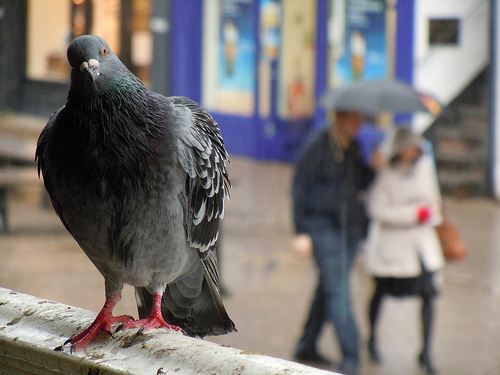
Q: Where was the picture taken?
A: It was taken at the street.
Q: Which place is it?
A: It is a street.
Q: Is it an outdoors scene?
A: Yes, it is outdoors.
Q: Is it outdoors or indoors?
A: It is outdoors.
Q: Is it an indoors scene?
A: No, it is outdoors.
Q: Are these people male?
A: No, they are both male and female.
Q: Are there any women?
A: Yes, there is a woman.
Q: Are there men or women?
A: Yes, there is a woman.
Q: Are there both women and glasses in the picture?
A: No, there is a woman but no glasses.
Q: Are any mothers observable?
A: No, there are no mothers.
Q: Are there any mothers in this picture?
A: No, there are no mothers.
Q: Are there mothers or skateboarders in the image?
A: No, there are no mothers or skateboarders.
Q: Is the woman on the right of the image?
A: Yes, the woman is on the right of the image.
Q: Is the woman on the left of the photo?
A: No, the woman is on the right of the image.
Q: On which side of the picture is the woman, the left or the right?
A: The woman is on the right of the image.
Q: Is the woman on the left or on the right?
A: The woman is on the right of the image.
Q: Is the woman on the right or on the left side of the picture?
A: The woman is on the right of the image.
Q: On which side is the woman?
A: The woman is on the right of the image.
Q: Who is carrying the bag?
A: The woman is carrying the bag.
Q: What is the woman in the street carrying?
A: The woman is carrying a bag.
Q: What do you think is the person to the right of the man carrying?
A: The woman is carrying a bag.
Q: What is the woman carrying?
A: The woman is carrying a bag.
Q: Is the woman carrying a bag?
A: Yes, the woman is carrying a bag.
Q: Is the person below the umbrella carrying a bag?
A: Yes, the woman is carrying a bag.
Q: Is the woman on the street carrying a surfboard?
A: No, the woman is carrying a bag.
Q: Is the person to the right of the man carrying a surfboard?
A: No, the woman is carrying a bag.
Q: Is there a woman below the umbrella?
A: Yes, there is a woman below the umbrella.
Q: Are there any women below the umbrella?
A: Yes, there is a woman below the umbrella.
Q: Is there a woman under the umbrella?
A: Yes, there is a woman under the umbrella.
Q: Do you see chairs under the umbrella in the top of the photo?
A: No, there is a woman under the umbrella.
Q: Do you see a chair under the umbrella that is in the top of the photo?
A: No, there is a woman under the umbrella.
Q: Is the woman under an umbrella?
A: Yes, the woman is under an umbrella.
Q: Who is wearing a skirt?
A: The woman is wearing a skirt.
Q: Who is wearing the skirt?
A: The woman is wearing a skirt.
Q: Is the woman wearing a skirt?
A: Yes, the woman is wearing a skirt.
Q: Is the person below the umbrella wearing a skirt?
A: Yes, the woman is wearing a skirt.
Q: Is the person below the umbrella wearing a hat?
A: No, the woman is wearing a skirt.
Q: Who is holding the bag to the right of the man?
A: The woman is holding the bag.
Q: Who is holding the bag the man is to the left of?
A: The woman is holding the bag.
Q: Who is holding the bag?
A: The woman is holding the bag.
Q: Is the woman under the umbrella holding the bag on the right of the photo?
A: Yes, the woman is holding the bag.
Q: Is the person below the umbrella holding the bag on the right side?
A: Yes, the woman is holding the bag.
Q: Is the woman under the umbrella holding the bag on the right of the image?
A: Yes, the woman is holding the bag.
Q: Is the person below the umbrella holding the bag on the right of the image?
A: Yes, the woman is holding the bag.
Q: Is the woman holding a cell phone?
A: No, the woman is holding the bag.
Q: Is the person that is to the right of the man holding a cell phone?
A: No, the woman is holding the bag.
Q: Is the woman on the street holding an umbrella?
A: Yes, the woman is holding an umbrella.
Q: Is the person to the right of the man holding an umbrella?
A: Yes, the woman is holding an umbrella.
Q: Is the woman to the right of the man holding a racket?
A: No, the woman is holding an umbrella.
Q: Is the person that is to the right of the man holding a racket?
A: No, the woman is holding an umbrella.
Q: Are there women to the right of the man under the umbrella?
A: Yes, there is a woman to the right of the man.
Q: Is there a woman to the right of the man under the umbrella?
A: Yes, there is a woman to the right of the man.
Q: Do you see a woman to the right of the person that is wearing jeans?
A: Yes, there is a woman to the right of the man.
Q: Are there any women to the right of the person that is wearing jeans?
A: Yes, there is a woman to the right of the man.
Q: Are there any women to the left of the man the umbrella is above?
A: No, the woman is to the right of the man.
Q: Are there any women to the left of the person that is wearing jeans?
A: No, the woman is to the right of the man.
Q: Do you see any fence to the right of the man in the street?
A: No, there is a woman to the right of the man.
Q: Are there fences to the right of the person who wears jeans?
A: No, there is a woman to the right of the man.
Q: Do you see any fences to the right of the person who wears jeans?
A: No, there is a woman to the right of the man.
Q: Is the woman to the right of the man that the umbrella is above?
A: Yes, the woman is to the right of the man.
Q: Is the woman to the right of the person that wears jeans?
A: Yes, the woman is to the right of the man.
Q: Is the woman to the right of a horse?
A: No, the woman is to the right of the man.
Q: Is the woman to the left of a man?
A: No, the woman is to the right of a man.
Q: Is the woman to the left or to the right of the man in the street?
A: The woman is to the right of the man.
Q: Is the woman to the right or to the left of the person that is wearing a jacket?
A: The woman is to the right of the man.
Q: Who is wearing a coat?
A: The woman is wearing a coat.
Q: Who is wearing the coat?
A: The woman is wearing a coat.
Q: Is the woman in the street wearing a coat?
A: Yes, the woman is wearing a coat.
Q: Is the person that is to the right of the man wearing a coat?
A: Yes, the woman is wearing a coat.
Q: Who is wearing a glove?
A: The woman is wearing a glove.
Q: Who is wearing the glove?
A: The woman is wearing a glove.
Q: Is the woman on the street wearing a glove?
A: Yes, the woman is wearing a glove.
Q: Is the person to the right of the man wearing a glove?
A: Yes, the woman is wearing a glove.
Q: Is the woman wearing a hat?
A: No, the woman is wearing a glove.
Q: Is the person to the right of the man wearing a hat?
A: No, the woman is wearing a glove.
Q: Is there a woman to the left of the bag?
A: Yes, there is a woman to the left of the bag.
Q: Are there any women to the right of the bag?
A: No, the woman is to the left of the bag.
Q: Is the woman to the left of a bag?
A: Yes, the woman is to the left of a bag.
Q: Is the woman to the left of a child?
A: No, the woman is to the left of a bag.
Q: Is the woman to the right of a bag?
A: No, the woman is to the left of a bag.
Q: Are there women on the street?
A: Yes, there is a woman on the street.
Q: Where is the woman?
A: The woman is in the street.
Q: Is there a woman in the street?
A: Yes, there is a woman in the street.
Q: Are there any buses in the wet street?
A: No, there is a woman in the street.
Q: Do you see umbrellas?
A: Yes, there is an umbrella.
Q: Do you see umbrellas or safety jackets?
A: Yes, there is an umbrella.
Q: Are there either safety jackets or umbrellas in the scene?
A: Yes, there is an umbrella.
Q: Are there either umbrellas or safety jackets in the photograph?
A: Yes, there is an umbrella.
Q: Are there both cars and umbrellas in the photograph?
A: No, there is an umbrella but no cars.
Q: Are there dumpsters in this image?
A: No, there are no dumpsters.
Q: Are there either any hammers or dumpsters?
A: No, there are no dumpsters or hammers.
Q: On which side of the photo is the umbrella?
A: The umbrella is on the right of the image.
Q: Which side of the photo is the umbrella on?
A: The umbrella is on the right of the image.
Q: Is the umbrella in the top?
A: Yes, the umbrella is in the top of the image.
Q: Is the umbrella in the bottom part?
A: No, the umbrella is in the top of the image.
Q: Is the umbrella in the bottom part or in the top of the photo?
A: The umbrella is in the top of the image.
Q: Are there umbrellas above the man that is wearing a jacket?
A: Yes, there is an umbrella above the man.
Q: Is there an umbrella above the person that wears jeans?
A: Yes, there is an umbrella above the man.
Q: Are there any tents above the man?
A: No, there is an umbrella above the man.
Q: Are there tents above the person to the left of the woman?
A: No, there is an umbrella above the man.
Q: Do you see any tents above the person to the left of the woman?
A: No, there is an umbrella above the man.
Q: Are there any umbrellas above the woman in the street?
A: Yes, there is an umbrella above the woman.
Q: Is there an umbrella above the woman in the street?
A: Yes, there is an umbrella above the woman.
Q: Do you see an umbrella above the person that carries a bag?
A: Yes, there is an umbrella above the woman.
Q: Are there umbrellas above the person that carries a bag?
A: Yes, there is an umbrella above the woman.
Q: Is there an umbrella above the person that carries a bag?
A: Yes, there is an umbrella above the woman.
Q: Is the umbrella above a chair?
A: No, the umbrella is above the woman.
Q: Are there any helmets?
A: No, there are no helmets.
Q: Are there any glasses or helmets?
A: No, there are no helmets or glasses.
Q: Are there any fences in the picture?
A: No, there are no fences.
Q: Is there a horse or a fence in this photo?
A: No, there are no fences or horses.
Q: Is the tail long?
A: Yes, the tail is long.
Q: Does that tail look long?
A: Yes, the tail is long.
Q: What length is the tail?
A: The tail is long.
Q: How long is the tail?
A: The tail is long.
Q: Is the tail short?
A: No, the tail is long.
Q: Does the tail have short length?
A: No, the tail is long.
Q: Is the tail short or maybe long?
A: The tail is long.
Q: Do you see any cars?
A: No, there are no cars.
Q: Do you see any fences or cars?
A: No, there are no cars or fences.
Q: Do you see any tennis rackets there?
A: No, there are no tennis rackets.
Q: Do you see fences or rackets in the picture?
A: No, there are no rackets or fences.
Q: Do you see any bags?
A: Yes, there is a bag.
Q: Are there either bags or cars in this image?
A: Yes, there is a bag.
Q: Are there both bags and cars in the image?
A: No, there is a bag but no cars.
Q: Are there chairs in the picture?
A: No, there are no chairs.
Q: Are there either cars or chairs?
A: No, there are no chairs or cars.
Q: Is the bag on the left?
A: No, the bag is on the right of the image.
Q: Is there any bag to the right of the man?
A: Yes, there is a bag to the right of the man.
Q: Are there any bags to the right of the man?
A: Yes, there is a bag to the right of the man.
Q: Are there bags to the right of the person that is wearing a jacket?
A: Yes, there is a bag to the right of the man.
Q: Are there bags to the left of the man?
A: No, the bag is to the right of the man.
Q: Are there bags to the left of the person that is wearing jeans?
A: No, the bag is to the right of the man.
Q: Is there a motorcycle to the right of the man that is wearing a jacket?
A: No, there is a bag to the right of the man.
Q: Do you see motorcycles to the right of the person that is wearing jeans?
A: No, there is a bag to the right of the man.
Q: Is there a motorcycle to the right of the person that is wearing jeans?
A: No, there is a bag to the right of the man.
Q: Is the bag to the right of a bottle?
A: No, the bag is to the right of the man.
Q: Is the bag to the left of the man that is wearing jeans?
A: No, the bag is to the right of the man.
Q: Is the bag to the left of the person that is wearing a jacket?
A: No, the bag is to the right of the man.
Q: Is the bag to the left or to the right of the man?
A: The bag is to the right of the man.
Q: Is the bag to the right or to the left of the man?
A: The bag is to the right of the man.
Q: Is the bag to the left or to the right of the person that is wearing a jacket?
A: The bag is to the right of the man.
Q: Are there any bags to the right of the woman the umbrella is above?
A: Yes, there is a bag to the right of the woman.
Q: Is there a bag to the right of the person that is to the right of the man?
A: Yes, there is a bag to the right of the woman.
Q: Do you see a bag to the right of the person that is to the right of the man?
A: Yes, there is a bag to the right of the woman.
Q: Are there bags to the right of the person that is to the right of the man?
A: Yes, there is a bag to the right of the woman.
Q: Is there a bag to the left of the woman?
A: No, the bag is to the right of the woman.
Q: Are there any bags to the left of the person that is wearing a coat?
A: No, the bag is to the right of the woman.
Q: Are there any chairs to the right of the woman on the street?
A: No, there is a bag to the right of the woman.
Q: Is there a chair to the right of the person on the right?
A: No, there is a bag to the right of the woman.